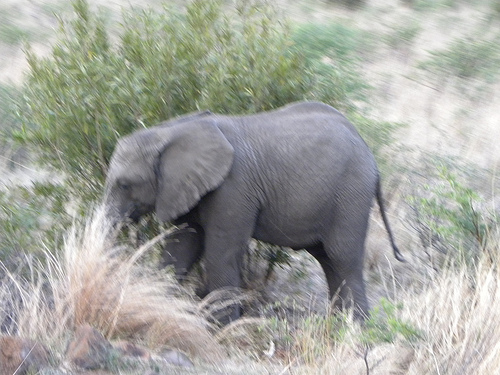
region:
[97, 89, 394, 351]
a small elephant standing by a bush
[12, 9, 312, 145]
a green bush next to the elephant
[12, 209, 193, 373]
some tall white grass by the elephant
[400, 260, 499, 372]
some more of the tall white grass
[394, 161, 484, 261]
another green bush behind the elephant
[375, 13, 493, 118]
some more bushes in the corner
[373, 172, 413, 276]
the tail of the elephant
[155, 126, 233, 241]
the big ear of the elephant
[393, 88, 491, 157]
some yellow grass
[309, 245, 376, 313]
the back legs of the elephant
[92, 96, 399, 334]
the elephant is facing left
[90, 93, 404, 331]
the elephant is grey in color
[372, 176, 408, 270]
the elephant's tail is thin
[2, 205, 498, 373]
the grass is high and in the front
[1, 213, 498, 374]
the grass is dry and long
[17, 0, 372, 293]
the tree is large in size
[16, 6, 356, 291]
the tree is behind the elephant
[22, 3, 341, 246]
the tree is full of leaves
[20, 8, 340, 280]
the tree is green in color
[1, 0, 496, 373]
the picture was taken outdoors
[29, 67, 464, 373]
an elephant walking in some undergrowth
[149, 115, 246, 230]
large floppy grey elephant ear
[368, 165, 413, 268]
skinny tail on an elephant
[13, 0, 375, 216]
green bush behind an elephant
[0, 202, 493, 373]
tufts of dried grass surround an elephant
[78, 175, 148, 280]
elephants trunk is hidden by grass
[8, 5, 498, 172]
background is blurred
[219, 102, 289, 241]
elephant has a wrinkly torso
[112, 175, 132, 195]
small black eye of an elephant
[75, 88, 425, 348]
elephant is walking off to the left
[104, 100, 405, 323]
Gray elephant in the weeds.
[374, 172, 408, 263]
Tail of gray elephant.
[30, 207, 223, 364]
Lots of weeds by elephant.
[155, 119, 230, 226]
Left ear of gray elephant.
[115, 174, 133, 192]
Left eye of gray elephant.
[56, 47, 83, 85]
Green leaves on a tree.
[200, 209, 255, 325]
Left front leg of gray elephant.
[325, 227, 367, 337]
Back right leg of elephant.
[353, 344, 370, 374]
Small twig sticking out of the ground.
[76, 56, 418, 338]
picture of elephant taken in the wild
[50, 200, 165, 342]
tall brown grass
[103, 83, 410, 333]
large grey elephant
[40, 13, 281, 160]
small green tree behind elephant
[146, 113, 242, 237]
large grey ears on elephant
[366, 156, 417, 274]
long grey tail of elephant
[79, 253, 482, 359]
large grassy area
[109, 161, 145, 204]
elephant's black eye on side of head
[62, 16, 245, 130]
tree with green leaves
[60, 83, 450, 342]
elephant walking through grassy area